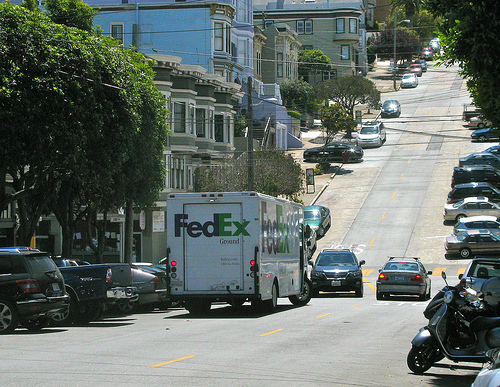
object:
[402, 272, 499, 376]
motorcycle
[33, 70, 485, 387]
street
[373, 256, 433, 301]
car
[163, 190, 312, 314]
truck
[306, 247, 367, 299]
suv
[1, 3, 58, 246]
tree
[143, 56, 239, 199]
home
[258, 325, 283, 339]
line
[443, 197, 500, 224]
car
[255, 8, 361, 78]
building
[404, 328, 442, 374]
front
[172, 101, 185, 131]
window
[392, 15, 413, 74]
streetlight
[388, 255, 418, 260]
rack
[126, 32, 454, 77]
lines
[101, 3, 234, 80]
house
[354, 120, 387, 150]
car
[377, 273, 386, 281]
brake light